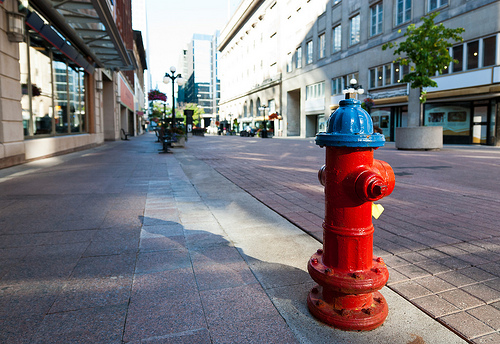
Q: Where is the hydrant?
A: By the street.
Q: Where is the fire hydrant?
A: On the sidewalk.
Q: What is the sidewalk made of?
A: Bricks.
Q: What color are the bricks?
A: Red.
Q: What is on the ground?
A: Shadow.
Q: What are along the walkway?
A: Stores.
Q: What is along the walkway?
A: Street lights.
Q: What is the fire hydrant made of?
A: Metal.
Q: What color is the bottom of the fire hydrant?
A: Red.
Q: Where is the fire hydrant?
A: Sidewalk.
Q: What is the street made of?
A: Bricks.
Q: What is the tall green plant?
A: Tree.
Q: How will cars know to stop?
A: Streetlights.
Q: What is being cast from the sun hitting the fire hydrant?
A: Shadow.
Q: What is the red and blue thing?
A: Fire Hydrant.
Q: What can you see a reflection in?
A: Windows.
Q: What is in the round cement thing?
A: Tree.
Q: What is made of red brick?
A: Street.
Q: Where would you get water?
A: Fire hydrant.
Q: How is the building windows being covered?
A: Awning.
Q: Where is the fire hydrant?
A: On the sidewalk.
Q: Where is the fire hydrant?
A: On the sidewalk.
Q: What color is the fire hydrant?
A: Red and blue.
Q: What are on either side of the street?
A: Buildings.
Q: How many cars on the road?
A: None.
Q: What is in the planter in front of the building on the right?
A: Tree.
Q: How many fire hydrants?
A: One.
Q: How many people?
A: None.